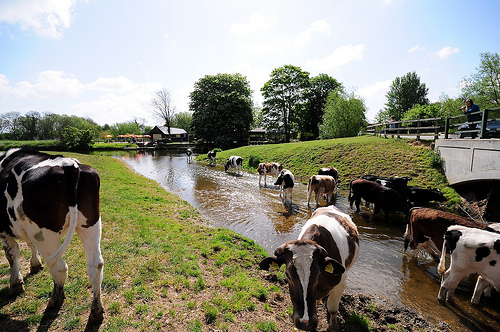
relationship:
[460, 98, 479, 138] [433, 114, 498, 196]
man near bridge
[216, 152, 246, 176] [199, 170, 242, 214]
cow drinking water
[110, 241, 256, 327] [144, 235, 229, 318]
grass has patches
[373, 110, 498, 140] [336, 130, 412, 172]
fence above field